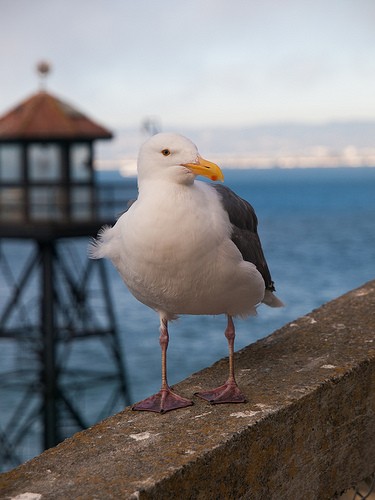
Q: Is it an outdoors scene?
A: Yes, it is outdoors.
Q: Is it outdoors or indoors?
A: It is outdoors.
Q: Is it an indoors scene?
A: No, it is outdoors.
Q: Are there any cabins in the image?
A: No, there are no cabins.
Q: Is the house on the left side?
A: Yes, the house is on the left of the image.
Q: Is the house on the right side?
A: No, the house is on the left of the image.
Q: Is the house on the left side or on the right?
A: The house is on the left of the image.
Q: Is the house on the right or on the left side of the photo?
A: The house is on the left of the image.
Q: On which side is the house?
A: The house is on the left of the image.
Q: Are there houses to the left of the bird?
A: Yes, there is a house to the left of the bird.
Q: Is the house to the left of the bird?
A: Yes, the house is to the left of the bird.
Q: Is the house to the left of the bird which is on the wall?
A: Yes, the house is to the left of the bird.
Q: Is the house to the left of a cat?
A: No, the house is to the left of the bird.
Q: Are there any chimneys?
A: No, there are no chimneys.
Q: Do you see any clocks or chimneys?
A: No, there are no chimneys or clocks.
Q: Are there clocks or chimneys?
A: No, there are no chimneys or clocks.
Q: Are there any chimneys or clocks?
A: No, there are no chimneys or clocks.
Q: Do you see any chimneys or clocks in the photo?
A: No, there are no chimneys or clocks.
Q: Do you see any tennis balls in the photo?
A: No, there are no tennis balls.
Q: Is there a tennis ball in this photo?
A: No, there are no tennis balls.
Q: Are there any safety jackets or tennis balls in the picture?
A: No, there are no tennis balls or safety jackets.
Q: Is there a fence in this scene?
A: Yes, there is a fence.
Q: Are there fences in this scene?
A: Yes, there is a fence.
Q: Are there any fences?
A: Yes, there is a fence.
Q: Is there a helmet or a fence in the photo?
A: Yes, there is a fence.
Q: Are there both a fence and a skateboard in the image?
A: No, there is a fence but no skateboards.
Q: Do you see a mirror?
A: No, there are no mirrors.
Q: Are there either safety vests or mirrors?
A: No, there are no mirrors or safety vests.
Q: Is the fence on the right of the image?
A: Yes, the fence is on the right of the image.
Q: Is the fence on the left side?
A: No, the fence is on the right of the image.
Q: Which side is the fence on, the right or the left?
A: The fence is on the right of the image.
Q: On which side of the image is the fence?
A: The fence is on the right of the image.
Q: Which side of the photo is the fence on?
A: The fence is on the right of the image.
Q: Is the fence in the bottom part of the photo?
A: Yes, the fence is in the bottom of the image.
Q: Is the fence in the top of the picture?
A: No, the fence is in the bottom of the image.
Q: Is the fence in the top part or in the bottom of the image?
A: The fence is in the bottom of the image.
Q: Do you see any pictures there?
A: No, there are no pictures.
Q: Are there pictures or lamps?
A: No, there are no pictures or lamps.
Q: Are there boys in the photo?
A: No, there are no boys.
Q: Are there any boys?
A: No, there are no boys.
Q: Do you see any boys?
A: No, there are no boys.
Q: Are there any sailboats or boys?
A: No, there are no boys or sailboats.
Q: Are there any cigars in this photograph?
A: No, there are no cigars.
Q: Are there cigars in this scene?
A: No, there are no cigars.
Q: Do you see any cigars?
A: No, there are no cigars.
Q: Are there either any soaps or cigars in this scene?
A: No, there are no cigars or soaps.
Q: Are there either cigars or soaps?
A: No, there are no cigars or soaps.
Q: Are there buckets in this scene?
A: No, there are no buckets.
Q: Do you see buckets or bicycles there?
A: No, there are no buckets or bicycles.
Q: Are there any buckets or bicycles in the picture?
A: No, there are no buckets or bicycles.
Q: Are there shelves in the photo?
A: No, there are no shelves.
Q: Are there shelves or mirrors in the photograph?
A: No, there are no shelves or mirrors.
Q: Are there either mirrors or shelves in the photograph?
A: No, there are no shelves or mirrors.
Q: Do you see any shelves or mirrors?
A: No, there are no shelves or mirrors.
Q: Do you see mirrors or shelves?
A: No, there are no shelves or mirrors.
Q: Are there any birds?
A: Yes, there is a bird.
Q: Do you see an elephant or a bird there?
A: Yes, there is a bird.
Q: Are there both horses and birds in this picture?
A: No, there is a bird but no horses.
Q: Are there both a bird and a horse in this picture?
A: No, there is a bird but no horses.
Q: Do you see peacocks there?
A: No, there are no peacocks.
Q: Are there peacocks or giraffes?
A: No, there are no peacocks or giraffes.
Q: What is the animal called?
A: The animal is a bird.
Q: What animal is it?
A: The animal is a bird.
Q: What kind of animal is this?
A: This is a bird.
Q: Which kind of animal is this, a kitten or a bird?
A: This is a bird.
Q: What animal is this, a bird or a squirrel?
A: This is a bird.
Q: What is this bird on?
A: The bird is on the wall.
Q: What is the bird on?
A: The bird is on the wall.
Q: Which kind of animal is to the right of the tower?
A: The animal is a bird.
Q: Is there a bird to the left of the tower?
A: No, the bird is to the right of the tower.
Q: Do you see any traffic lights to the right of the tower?
A: No, there is a bird to the right of the tower.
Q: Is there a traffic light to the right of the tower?
A: No, there is a bird to the right of the tower.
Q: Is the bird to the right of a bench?
A: No, the bird is to the right of a tower.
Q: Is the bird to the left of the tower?
A: No, the bird is to the right of the tower.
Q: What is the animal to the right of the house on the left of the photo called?
A: The animal is a bird.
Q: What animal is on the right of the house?
A: The animal is a bird.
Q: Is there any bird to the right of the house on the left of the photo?
A: Yes, there is a bird to the right of the house.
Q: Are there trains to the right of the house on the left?
A: No, there is a bird to the right of the house.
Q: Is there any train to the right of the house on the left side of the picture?
A: No, there is a bird to the right of the house.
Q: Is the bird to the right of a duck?
A: No, the bird is to the right of a house.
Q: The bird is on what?
A: The bird is on the wall.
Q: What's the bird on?
A: The bird is on the wall.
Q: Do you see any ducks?
A: No, there are no ducks.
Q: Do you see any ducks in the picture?
A: No, there are no ducks.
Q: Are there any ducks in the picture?
A: No, there are no ducks.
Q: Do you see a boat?
A: No, there are no boats.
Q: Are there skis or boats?
A: No, there are no boats or skis.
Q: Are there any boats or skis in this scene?
A: No, there are no boats or skis.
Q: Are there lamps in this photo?
A: No, there are no lamps.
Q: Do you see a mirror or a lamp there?
A: No, there are no lamps or mirrors.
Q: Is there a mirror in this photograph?
A: No, there are no mirrors.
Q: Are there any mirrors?
A: No, there are no mirrors.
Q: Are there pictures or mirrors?
A: No, there are no mirrors or pictures.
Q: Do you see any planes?
A: No, there are no planes.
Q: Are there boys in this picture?
A: No, there are no boys.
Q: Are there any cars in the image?
A: No, there are no cars.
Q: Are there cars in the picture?
A: No, there are no cars.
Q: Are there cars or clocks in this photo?
A: No, there are no cars or clocks.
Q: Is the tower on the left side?
A: Yes, the tower is on the left of the image.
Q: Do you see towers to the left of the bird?
A: Yes, there is a tower to the left of the bird.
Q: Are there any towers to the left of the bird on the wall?
A: Yes, there is a tower to the left of the bird.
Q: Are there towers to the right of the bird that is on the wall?
A: No, the tower is to the left of the bird.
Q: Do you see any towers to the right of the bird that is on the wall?
A: No, the tower is to the left of the bird.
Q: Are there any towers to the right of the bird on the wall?
A: No, the tower is to the left of the bird.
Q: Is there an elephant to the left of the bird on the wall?
A: No, there is a tower to the left of the bird.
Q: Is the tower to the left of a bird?
A: Yes, the tower is to the left of a bird.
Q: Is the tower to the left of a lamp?
A: No, the tower is to the left of a bird.